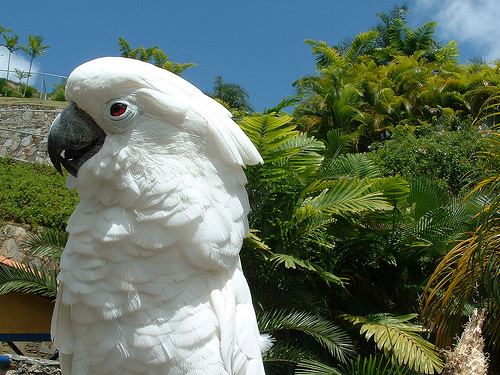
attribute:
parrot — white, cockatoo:
[45, 55, 264, 365]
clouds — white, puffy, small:
[415, 5, 496, 52]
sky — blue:
[0, 3, 499, 57]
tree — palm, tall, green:
[378, 11, 456, 64]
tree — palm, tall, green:
[306, 33, 379, 65]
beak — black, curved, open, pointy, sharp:
[48, 102, 105, 178]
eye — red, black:
[111, 105, 126, 120]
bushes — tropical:
[273, 107, 499, 369]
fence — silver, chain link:
[5, 65, 68, 105]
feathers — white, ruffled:
[143, 102, 240, 258]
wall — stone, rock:
[7, 107, 48, 164]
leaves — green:
[301, 177, 419, 216]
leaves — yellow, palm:
[418, 226, 494, 320]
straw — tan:
[439, 315, 487, 373]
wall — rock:
[2, 224, 56, 276]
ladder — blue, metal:
[2, 325, 59, 374]